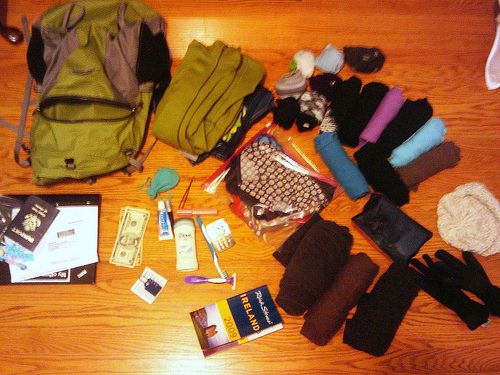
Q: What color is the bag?
A: Green.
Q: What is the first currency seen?
A: Us.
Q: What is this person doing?
A: Traveling.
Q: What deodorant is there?
A: Dove.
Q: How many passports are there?
A: One.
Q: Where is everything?
A: On a table.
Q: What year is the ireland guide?
A: 2009.